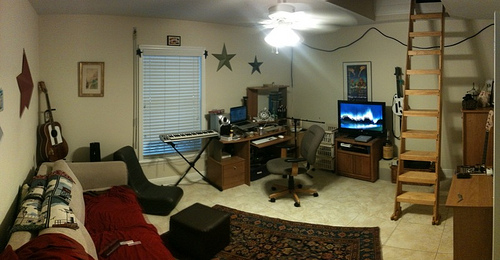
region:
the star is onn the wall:
[211, 39, 238, 74]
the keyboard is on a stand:
[174, 131, 206, 163]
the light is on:
[264, 26, 299, 53]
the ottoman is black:
[196, 206, 212, 234]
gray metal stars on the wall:
[211, 38, 271, 80]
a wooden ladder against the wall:
[404, 6, 451, 258]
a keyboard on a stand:
[143, 117, 225, 187]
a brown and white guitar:
[31, 70, 79, 170]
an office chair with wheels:
[254, 94, 333, 206]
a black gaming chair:
[111, 143, 188, 220]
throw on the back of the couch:
[31, 164, 78, 256]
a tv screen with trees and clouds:
[325, 80, 415, 132]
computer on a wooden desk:
[211, 87, 317, 155]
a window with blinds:
[126, 29, 231, 164]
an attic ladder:
[388, 8, 448, 228]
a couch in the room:
[4, 157, 179, 259]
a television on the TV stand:
[336, 97, 388, 137]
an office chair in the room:
[263, 121, 328, 209]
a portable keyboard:
[157, 126, 223, 190]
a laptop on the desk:
[227, 101, 257, 130]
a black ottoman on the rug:
[168, 200, 233, 257]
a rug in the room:
[142, 202, 387, 259]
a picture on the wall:
[74, 58, 106, 100]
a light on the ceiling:
[262, 25, 306, 50]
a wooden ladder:
[389, 0, 447, 225]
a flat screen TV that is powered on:
[333, 99, 383, 133]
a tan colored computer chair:
[261, 122, 328, 207]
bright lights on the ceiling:
[259, 0, 312, 52]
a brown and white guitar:
[34, 78, 69, 158]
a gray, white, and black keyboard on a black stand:
[158, 128, 221, 193]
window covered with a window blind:
[134, 45, 205, 161]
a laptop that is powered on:
[227, 103, 258, 133]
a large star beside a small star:
[212, 42, 268, 76]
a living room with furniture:
[5, 3, 494, 258]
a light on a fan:
[254, 14, 311, 52]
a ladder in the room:
[390, 6, 447, 229]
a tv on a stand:
[337, 90, 387, 185]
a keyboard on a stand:
[157, 127, 222, 189]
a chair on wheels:
[267, 121, 324, 206]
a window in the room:
[136, 37, 206, 154]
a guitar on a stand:
[36, 76, 70, 160]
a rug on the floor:
[154, 199, 388, 259]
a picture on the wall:
[72, 55, 110, 102]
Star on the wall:
[208, 39, 240, 78]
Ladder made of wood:
[390, 8, 447, 225]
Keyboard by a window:
[154, 124, 226, 199]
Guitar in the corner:
[27, 74, 83, 166]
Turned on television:
[337, 100, 387, 128]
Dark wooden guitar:
[38, 81, 72, 158]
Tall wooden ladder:
[391, 3, 444, 223]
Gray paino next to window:
[159, 129, 219, 191]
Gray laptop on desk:
[228, 108, 254, 130]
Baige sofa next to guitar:
[1, 160, 175, 258]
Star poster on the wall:
[211, 43, 236, 73]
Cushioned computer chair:
[261, 124, 323, 206]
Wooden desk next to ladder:
[446, 170, 498, 255]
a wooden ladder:
[393, 3, 443, 228]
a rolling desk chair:
[268, 125, 323, 207]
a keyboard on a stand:
[161, 126, 216, 188]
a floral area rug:
[166, 212, 384, 259]